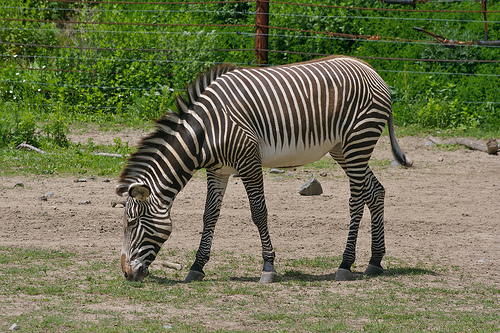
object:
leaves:
[252, 0, 387, 60]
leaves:
[281, 0, 431, 64]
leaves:
[121, 17, 241, 63]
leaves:
[71, 16, 191, 76]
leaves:
[1, 6, 156, 78]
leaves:
[418, 75, 465, 118]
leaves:
[367, 53, 413, 72]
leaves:
[404, 40, 441, 124]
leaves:
[409, 40, 468, 101]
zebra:
[114, 55, 414, 284]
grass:
[1, 243, 498, 333]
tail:
[388, 103, 414, 167]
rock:
[298, 177, 323, 196]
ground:
[1, 118, 497, 332]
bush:
[1, 1, 499, 171]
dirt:
[0, 177, 498, 260]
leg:
[183, 166, 230, 284]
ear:
[116, 183, 130, 197]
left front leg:
[233, 147, 277, 284]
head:
[116, 182, 187, 281]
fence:
[0, 0, 500, 131]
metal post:
[253, 0, 269, 67]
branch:
[12, 137, 138, 177]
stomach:
[257, 139, 342, 167]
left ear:
[129, 183, 151, 200]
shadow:
[154, 267, 439, 287]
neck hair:
[118, 115, 176, 185]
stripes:
[217, 76, 373, 146]